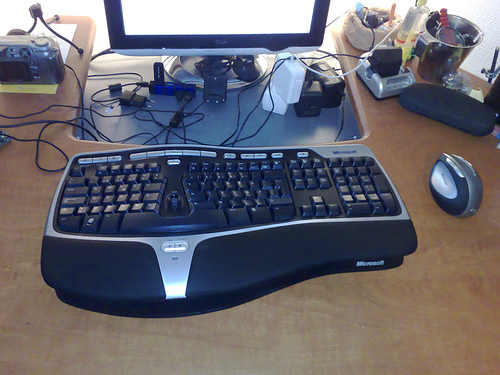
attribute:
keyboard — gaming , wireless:
[37, 143, 416, 315]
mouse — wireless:
[414, 145, 484, 215]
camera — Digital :
[3, 39, 64, 92]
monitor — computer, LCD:
[119, 4, 330, 35]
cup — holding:
[405, 18, 485, 94]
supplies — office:
[424, 13, 472, 43]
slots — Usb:
[144, 67, 214, 121]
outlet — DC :
[186, 70, 244, 116]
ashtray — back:
[348, 19, 395, 49]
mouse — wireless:
[433, 159, 482, 217]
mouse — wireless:
[438, 150, 480, 223]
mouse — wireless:
[431, 148, 484, 219]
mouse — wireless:
[419, 151, 485, 226]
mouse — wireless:
[420, 158, 481, 208]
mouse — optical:
[418, 140, 484, 214]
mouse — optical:
[425, 152, 485, 212]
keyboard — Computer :
[64, 150, 394, 227]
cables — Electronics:
[99, 68, 340, 137]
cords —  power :
[123, 69, 310, 123]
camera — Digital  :
[0, 42, 67, 92]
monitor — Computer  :
[122, 2, 319, 40]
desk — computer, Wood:
[14, 25, 479, 361]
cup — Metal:
[422, 12, 469, 92]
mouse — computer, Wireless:
[417, 142, 485, 226]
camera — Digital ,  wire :
[10, 37, 60, 87]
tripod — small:
[9, 4, 81, 48]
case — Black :
[401, 85, 484, 131]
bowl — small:
[345, 5, 403, 52]